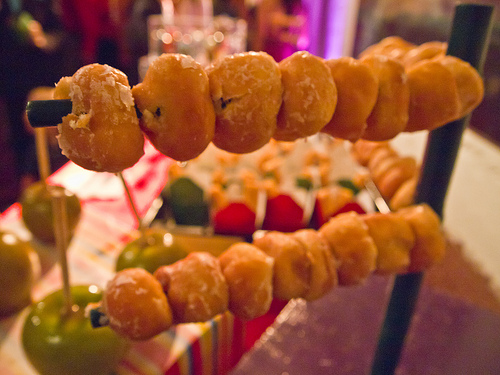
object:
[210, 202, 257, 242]
red boxes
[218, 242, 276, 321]
doughnut hole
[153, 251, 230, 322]
pastry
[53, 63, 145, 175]
donut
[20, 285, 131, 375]
apple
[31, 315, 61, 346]
light gleaming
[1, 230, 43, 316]
apple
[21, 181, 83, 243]
apple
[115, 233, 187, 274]
apple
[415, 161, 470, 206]
ground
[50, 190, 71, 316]
candy apple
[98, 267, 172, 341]
doughnut hole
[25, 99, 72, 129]
black pole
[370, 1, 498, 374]
black pole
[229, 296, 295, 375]
edge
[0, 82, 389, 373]
table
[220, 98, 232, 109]
hole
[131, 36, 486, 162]
donut holes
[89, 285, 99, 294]
light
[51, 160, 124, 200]
light